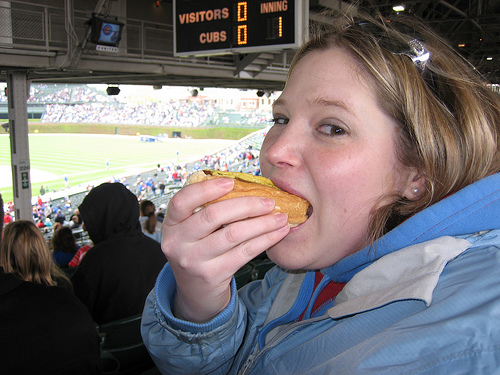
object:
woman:
[138, 10, 500, 375]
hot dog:
[186, 168, 312, 230]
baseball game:
[1, 124, 265, 201]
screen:
[173, 0, 290, 43]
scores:
[233, 0, 252, 46]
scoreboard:
[174, 1, 301, 53]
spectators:
[2, 84, 277, 125]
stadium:
[4, 3, 499, 375]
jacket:
[139, 241, 500, 373]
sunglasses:
[364, 18, 431, 54]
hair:
[286, 13, 500, 263]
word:
[179, 5, 231, 26]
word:
[199, 30, 230, 45]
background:
[1, 84, 280, 233]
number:
[237, 2, 250, 46]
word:
[255, 0, 289, 14]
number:
[275, 17, 286, 40]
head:
[259, 10, 499, 271]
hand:
[159, 178, 292, 291]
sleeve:
[138, 263, 271, 373]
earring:
[412, 188, 422, 195]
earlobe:
[403, 182, 424, 202]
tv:
[90, 22, 124, 47]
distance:
[1, 84, 283, 204]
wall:
[1, 0, 340, 81]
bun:
[190, 168, 311, 225]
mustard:
[211, 169, 239, 180]